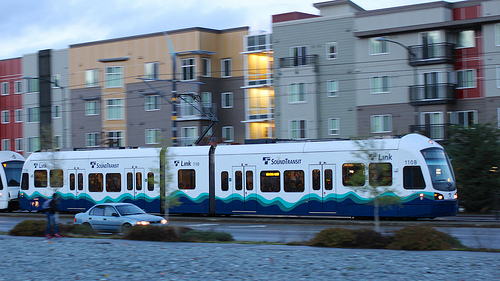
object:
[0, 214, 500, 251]
road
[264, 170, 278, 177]
light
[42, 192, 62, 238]
person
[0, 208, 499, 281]
ground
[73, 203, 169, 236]
car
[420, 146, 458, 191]
windsheild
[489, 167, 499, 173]
light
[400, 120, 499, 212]
bushes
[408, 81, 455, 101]
railing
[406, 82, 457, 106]
balcony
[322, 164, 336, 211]
door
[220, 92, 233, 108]
window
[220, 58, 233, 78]
window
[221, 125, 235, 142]
window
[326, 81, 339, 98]
window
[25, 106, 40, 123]
windows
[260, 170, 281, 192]
window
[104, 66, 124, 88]
windows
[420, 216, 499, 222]
track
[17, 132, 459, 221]
train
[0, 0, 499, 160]
building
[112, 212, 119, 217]
mirror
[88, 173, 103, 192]
window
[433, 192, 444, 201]
light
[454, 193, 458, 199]
light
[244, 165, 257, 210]
door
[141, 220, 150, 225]
headlight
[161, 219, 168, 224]
headlight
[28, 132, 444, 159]
top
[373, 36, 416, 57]
street lamp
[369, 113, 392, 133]
window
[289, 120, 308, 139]
window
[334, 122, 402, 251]
tree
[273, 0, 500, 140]
gray building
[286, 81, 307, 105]
window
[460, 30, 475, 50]
window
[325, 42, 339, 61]
window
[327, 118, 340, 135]
window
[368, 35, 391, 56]
window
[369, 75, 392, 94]
window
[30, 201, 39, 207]
reflection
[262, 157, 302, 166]
writing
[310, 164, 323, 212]
door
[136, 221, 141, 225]
light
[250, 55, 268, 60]
light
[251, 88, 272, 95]
light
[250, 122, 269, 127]
light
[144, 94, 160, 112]
window